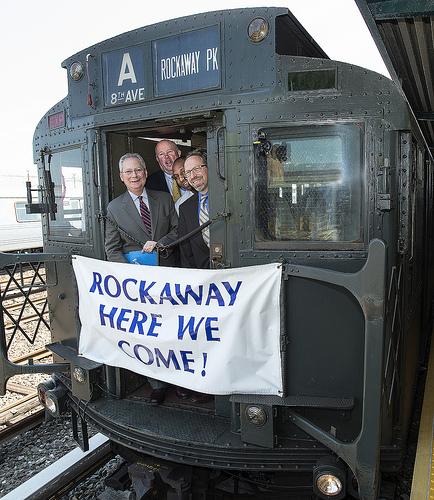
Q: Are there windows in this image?
A: Yes, there is a window.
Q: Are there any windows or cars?
A: Yes, there is a window.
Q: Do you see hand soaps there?
A: No, there are no hand soaps.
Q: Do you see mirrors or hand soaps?
A: No, there are no hand soaps or mirrors.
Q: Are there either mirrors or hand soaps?
A: No, there are no hand soaps or mirrors.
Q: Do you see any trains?
A: Yes, there is a train.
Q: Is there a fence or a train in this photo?
A: Yes, there is a train.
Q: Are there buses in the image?
A: No, there are no buses.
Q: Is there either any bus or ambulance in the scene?
A: No, there are no buses or ambulances.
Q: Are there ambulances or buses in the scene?
A: No, there are no buses or ambulances.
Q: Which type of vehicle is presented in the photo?
A: The vehicle is a train.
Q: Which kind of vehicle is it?
A: The vehicle is a train.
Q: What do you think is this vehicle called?
A: That is a train.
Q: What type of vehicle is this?
A: That is a train.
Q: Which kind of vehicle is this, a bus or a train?
A: That is a train.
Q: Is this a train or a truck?
A: This is a train.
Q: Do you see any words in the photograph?
A: Yes, there are words.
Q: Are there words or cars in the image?
A: Yes, there are words.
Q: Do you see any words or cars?
A: Yes, there are words.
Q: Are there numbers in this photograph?
A: No, there are no numbers.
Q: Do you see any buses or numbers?
A: No, there are no numbers or buses.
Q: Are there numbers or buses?
A: No, there are no numbers or buses.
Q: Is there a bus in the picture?
A: No, there are no buses.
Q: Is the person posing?
A: Yes, the person is posing.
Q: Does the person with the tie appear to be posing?
A: Yes, the person is posing.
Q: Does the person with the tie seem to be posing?
A: Yes, the person is posing.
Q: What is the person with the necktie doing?
A: The person is posing.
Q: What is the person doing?
A: The person is posing.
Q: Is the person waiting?
A: No, the person is posing.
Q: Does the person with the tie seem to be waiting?
A: No, the person is posing.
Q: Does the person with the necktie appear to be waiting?
A: No, the person is posing.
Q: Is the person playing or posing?
A: The person is posing.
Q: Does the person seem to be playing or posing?
A: The person is posing.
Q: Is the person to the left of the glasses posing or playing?
A: The person is posing.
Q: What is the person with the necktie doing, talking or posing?
A: The person is posing.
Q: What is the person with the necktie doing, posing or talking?
A: The person is posing.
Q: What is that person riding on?
A: The person is riding on a train.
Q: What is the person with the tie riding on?
A: The person is riding on a train.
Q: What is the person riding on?
A: The person is riding on a train.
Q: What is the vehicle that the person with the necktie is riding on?
A: The vehicle is a train.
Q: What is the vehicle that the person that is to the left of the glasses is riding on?
A: The vehicle is a train.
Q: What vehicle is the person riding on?
A: The person is riding on a train.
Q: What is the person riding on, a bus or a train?
A: The person is riding on a train.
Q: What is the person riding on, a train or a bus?
A: The person is riding on a train.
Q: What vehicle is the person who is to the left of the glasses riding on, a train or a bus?
A: The person is riding on a train.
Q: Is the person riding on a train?
A: Yes, the person is riding on a train.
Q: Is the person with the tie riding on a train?
A: Yes, the person is riding on a train.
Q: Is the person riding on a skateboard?
A: No, the person is riding on a train.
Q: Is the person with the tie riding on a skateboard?
A: No, the person is riding on a train.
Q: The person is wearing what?
A: The person is wearing glasses.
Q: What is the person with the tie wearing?
A: The person is wearing glasses.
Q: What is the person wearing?
A: The person is wearing glasses.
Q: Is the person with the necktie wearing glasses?
A: Yes, the person is wearing glasses.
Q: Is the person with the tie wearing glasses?
A: Yes, the person is wearing glasses.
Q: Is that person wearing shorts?
A: No, the person is wearing glasses.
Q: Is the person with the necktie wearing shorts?
A: No, the person is wearing glasses.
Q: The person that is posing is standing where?
A: The person is standing in the doorway.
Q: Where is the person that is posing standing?
A: The person is standing in the doorway.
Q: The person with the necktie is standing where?
A: The person is standing in the doorway.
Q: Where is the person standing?
A: The person is standing in the doorway.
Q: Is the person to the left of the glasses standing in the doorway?
A: Yes, the person is standing in the doorway.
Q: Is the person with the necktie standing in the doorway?
A: Yes, the person is standing in the doorway.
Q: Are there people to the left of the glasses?
A: Yes, there is a person to the left of the glasses.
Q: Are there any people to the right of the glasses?
A: No, the person is to the left of the glasses.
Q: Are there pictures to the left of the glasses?
A: No, there is a person to the left of the glasses.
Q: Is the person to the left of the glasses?
A: Yes, the person is to the left of the glasses.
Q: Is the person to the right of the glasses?
A: No, the person is to the left of the glasses.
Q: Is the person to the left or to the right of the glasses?
A: The person is to the left of the glasses.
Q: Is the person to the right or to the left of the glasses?
A: The person is to the left of the glasses.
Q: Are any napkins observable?
A: No, there are no napkins.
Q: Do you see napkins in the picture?
A: No, there are no napkins.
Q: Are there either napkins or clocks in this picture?
A: No, there are no napkins or clocks.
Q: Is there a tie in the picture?
A: Yes, there is a tie.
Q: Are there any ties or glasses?
A: Yes, there is a tie.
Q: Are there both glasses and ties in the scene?
A: Yes, there are both a tie and glasses.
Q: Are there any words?
A: Yes, there are words.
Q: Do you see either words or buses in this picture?
A: Yes, there are words.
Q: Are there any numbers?
A: No, there are no numbers.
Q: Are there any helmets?
A: No, there are no helmets.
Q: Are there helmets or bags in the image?
A: No, there are no helmets or bags.